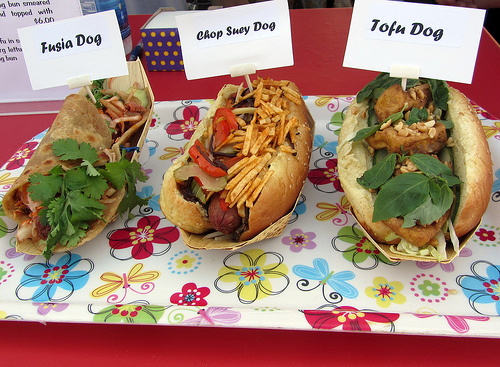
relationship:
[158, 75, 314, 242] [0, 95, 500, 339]
bread on board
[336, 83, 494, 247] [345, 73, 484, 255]
bun on bun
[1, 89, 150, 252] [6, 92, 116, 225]
bun rolled in tortilla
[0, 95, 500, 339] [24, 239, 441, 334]
board has flowers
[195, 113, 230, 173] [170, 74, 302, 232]
tomatoes on hot dog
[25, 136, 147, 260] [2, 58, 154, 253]
cilantro on top of hot dog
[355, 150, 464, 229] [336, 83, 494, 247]
basil leaves on top of bun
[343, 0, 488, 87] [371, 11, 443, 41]
white sign has letters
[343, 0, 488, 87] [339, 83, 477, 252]
white sign on hot dog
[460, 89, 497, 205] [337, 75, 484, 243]
sesame seeds on side of bun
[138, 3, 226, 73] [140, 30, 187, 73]
box has dots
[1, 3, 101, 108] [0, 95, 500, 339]
menu sitting on board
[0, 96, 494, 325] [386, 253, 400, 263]
board has part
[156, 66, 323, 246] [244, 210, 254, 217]
bread has part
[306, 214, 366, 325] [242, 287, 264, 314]
cloth has part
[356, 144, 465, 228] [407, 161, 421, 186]
basil leaves has part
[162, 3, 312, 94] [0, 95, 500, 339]
sign for board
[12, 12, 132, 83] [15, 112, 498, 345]
sign for tray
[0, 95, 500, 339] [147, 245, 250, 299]
board has part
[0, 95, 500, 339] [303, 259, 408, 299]
board has part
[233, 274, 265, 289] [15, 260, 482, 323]
flower on table cloth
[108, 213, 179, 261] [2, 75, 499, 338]
flower on table cloth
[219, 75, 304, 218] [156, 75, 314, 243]
potatoes on hot dog